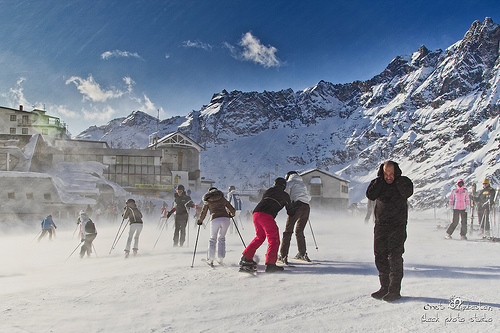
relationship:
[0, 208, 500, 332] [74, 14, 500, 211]
snow on mountains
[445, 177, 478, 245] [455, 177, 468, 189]
person has head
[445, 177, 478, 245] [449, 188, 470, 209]
person has body